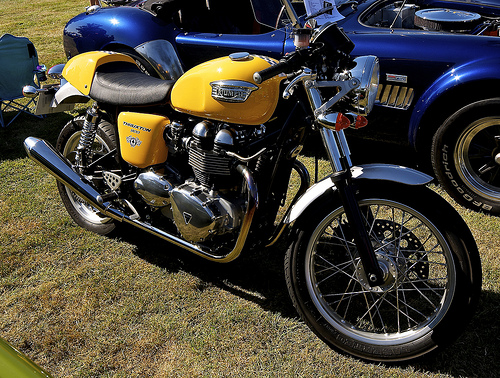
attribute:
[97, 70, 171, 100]
seat — black, leather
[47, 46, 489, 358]
motorcycle — parked, yellow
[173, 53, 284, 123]
tank — yellow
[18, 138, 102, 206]
pipe — silver, angled, cone shaped, chrome, shiny, long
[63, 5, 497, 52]
car — blue, vintage, shiny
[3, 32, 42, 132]
chair — foldable, folding, fabrice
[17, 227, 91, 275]
grass — brown, green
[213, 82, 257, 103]
panel — raised, metal, chrome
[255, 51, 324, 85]
handlebars — black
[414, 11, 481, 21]
lid — flat, blue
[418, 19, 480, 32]
wheel — round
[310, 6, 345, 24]
paper — white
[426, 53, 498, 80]
covering — curved, blue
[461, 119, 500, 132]
covering — silver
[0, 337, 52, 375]
surface — green, painted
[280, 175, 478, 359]
tire — black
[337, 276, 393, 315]
spokes — chrome, shiny